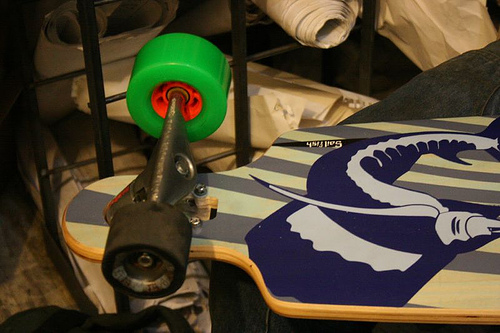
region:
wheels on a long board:
[63, 36, 258, 310]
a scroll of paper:
[250, 3, 374, 56]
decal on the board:
[237, 135, 497, 302]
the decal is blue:
[222, 105, 497, 304]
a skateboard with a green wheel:
[70, 18, 235, 315]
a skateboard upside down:
[38, 94, 492, 318]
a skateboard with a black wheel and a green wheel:
[91, 27, 236, 312]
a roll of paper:
[271, 0, 373, 63]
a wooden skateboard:
[28, 109, 462, 313]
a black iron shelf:
[53, 4, 381, 184]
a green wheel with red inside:
[120, 47, 240, 139]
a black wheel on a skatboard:
[78, 195, 220, 305]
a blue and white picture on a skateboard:
[353, 125, 483, 331]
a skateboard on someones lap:
[105, 40, 497, 291]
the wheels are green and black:
[87, 32, 241, 284]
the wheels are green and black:
[100, 59, 323, 331]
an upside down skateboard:
[54, 29, 499, 319]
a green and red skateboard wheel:
[120, 32, 234, 151]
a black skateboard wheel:
[96, 200, 191, 299]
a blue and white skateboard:
[54, 104, 499, 324]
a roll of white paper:
[251, 0, 368, 57]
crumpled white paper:
[365, 0, 497, 77]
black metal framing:
[35, 7, 254, 312]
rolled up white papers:
[70, 42, 382, 154]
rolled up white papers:
[28, 134, 203, 324]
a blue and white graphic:
[242, 129, 496, 304]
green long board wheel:
[127, 34, 231, 142]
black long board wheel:
[103, 195, 191, 300]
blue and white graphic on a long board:
[280, 133, 499, 308]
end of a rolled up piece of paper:
[256, 2, 364, 49]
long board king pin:
[170, 155, 192, 177]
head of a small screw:
[191, 180, 208, 195]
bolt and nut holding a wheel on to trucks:
[134, 252, 154, 269]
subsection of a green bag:
[5, 305, 189, 331]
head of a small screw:
[188, 215, 202, 225]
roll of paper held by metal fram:
[34, 0, 104, 170]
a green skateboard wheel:
[62, 7, 297, 168]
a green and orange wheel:
[101, 34, 361, 174]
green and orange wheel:
[94, 20, 321, 147]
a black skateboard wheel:
[24, 150, 272, 330]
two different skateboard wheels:
[102, 2, 260, 319]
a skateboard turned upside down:
[37, 17, 498, 327]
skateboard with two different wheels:
[73, 16, 462, 330]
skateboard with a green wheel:
[47, 10, 498, 322]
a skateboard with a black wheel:
[19, 20, 452, 331]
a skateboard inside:
[55, 17, 497, 322]